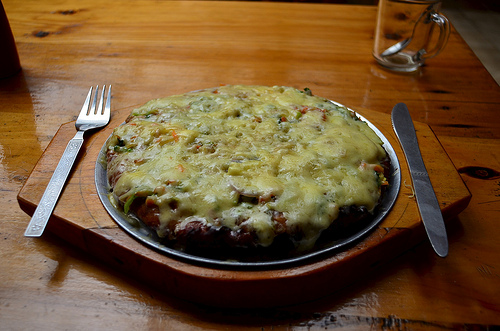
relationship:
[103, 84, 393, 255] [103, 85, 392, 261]
pizza has cheese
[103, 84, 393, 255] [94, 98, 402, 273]
pizza on pan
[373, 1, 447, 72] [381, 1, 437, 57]
glass has spoon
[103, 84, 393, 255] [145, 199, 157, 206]
pizza has tomato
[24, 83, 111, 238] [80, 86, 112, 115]
fork with tines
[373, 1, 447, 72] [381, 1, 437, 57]
glass with spoon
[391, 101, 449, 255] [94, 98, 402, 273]
knife with pan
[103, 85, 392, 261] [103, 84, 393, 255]
cheese on pizza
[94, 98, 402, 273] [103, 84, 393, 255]
pan of pizza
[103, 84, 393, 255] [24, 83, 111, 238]
pizza with fork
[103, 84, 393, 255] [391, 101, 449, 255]
pizza with knife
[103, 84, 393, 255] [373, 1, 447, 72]
pizza with glass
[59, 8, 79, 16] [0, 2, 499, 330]
knot in table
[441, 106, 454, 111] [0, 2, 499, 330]
spot on table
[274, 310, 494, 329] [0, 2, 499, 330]
line on table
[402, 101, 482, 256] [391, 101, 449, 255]
edge of knife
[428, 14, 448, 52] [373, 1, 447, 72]
handle of glass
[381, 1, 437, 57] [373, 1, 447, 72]
spoon in glass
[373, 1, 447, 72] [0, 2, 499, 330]
glass on table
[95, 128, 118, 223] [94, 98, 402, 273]
edge of pan